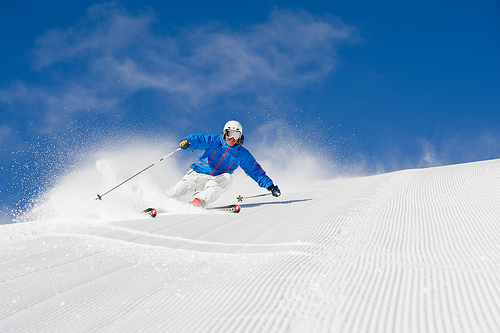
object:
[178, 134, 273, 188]
parka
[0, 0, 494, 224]
blue sky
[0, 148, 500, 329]
snow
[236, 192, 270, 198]
ski pole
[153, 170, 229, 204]
pants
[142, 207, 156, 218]
skis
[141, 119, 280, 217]
blue coat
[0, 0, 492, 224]
cloud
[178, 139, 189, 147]
hand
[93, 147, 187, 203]
ski pole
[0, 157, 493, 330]
ground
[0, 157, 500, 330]
hill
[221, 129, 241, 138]
goggles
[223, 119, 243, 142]
helmet